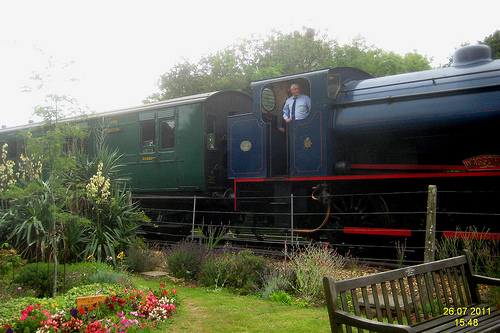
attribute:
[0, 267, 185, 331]
bed — multicolored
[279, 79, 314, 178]
man — old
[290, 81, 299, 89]
hair — grey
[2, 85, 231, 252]
car — green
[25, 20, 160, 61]
grey sky — overcast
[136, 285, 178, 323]
flowers — pictured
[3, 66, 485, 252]
car — green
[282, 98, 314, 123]
shirt — blue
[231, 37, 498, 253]
train car — blue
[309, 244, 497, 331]
bench — wooden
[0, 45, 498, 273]
train — blue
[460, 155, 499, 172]
logo — red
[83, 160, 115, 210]
flowers — yellow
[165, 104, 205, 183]
paint — green